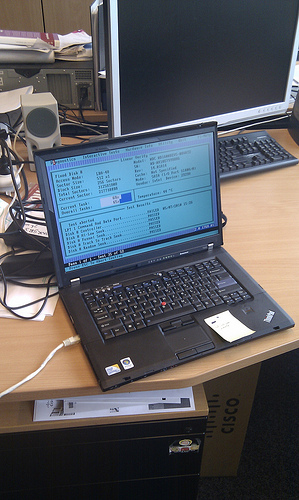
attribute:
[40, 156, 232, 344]
computer — black, sitting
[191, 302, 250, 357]
post it — yellow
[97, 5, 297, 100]
monitor — large, on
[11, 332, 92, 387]
cable — white, bundled, connected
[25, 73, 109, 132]
speaker — beige, white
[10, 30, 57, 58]
textbook — sitting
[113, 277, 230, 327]
keyboard — black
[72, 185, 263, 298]
laptop — on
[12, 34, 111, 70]
papers — stacked, white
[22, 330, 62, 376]
supply — white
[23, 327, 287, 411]
desk — brown, wooden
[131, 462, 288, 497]
floor — black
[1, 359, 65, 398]
cord — white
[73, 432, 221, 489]
cabinet — black, under